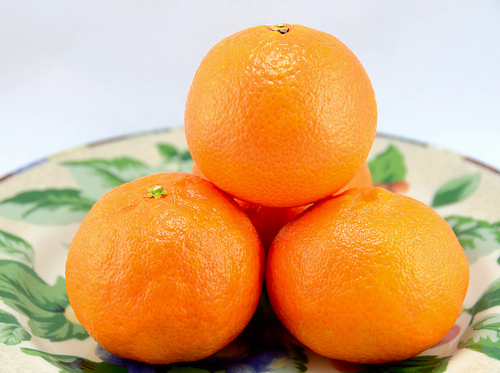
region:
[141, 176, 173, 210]
a small green stem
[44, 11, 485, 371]
a few round fruits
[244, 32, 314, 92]
a few dimples in a peel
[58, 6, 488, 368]
some bright orange fruits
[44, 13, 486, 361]
a stack of oranges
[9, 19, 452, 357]
some oranges on plate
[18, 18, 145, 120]
a plain white background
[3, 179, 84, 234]
a green painted leaf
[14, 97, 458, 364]
a floral design on a plate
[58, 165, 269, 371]
whole fruit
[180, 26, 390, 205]
the orange is round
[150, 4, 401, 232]
the orange is orange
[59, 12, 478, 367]
there are three oranges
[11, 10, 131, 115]
the background is white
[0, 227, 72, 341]
the design is green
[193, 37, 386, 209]
the orange is smooth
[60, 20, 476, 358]
the orange is balancing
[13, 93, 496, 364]
the plate is round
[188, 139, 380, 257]
the orange is behind the others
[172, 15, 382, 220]
the orange is shiny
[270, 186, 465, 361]
an orange on a plate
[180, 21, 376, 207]
an orange sitting on top of three oranges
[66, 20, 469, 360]
four oranges on a plate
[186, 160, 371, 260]
an orange is behind the other oranges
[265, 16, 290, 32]
a nub on top of the orange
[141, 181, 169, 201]
a green nub on top of the orange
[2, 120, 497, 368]
a plate under the oranges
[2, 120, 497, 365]
the plate has a blue edge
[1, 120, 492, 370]
the plate has a green leaf motif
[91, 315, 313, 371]
the bowl of the plate has a blue decoration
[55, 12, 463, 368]
oranges on a plate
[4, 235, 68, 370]
the plate has green leaves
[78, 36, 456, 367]
the oranges are stacked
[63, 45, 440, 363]
the oranges are orange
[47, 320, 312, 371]
the plate has a floral design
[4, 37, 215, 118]
the background is white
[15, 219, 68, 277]
the plate has white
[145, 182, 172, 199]
the orange has green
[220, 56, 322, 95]
the orange peel looks shiny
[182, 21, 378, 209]
a small ripe orange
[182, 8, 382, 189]
a piece of citrus fruit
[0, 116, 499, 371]
fruit on a decorative plate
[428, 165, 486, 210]
green leaves on decorative plate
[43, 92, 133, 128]
white table underneath plate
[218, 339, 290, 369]
blue floral decoration on plate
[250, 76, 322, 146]
small pits in orange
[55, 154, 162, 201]
large leaf decoration on plate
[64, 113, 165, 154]
dark edge of plate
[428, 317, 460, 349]
pink flower on plate